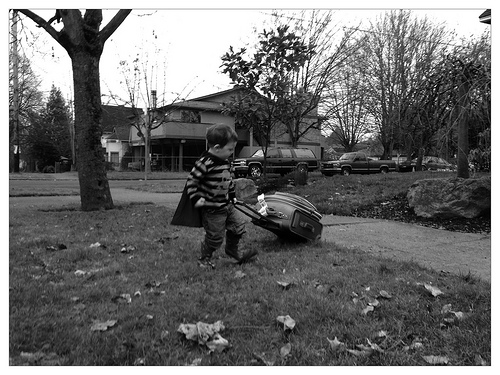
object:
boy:
[185, 117, 247, 262]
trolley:
[231, 199, 319, 245]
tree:
[75, 8, 115, 211]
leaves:
[278, 313, 300, 329]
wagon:
[230, 146, 327, 175]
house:
[91, 82, 336, 166]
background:
[10, 4, 492, 367]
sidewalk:
[30, 172, 493, 278]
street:
[13, 159, 487, 174]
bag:
[233, 171, 264, 200]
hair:
[203, 121, 241, 146]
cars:
[323, 149, 396, 172]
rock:
[408, 169, 499, 223]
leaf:
[175, 317, 229, 354]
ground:
[14, 163, 489, 367]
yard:
[8, 162, 492, 365]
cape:
[168, 178, 207, 230]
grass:
[11, 198, 491, 364]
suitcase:
[230, 192, 325, 246]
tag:
[249, 197, 269, 216]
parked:
[229, 138, 468, 197]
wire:
[256, 12, 476, 60]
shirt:
[185, 154, 237, 207]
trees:
[453, 40, 490, 176]